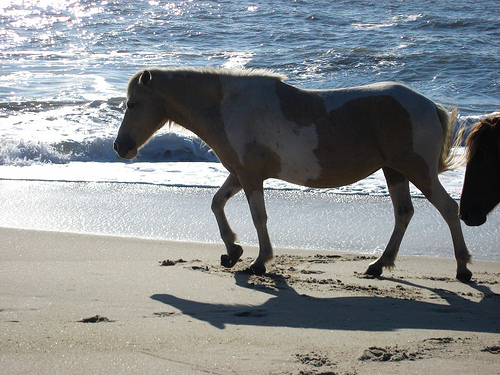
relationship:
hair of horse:
[187, 86, 445, 211] [83, 29, 494, 318]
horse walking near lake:
[109, 66, 476, 284] [0, 1, 499, 184]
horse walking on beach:
[109, 66, 476, 284] [0, 0, 499, 370]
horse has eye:
[66, 39, 490, 309] [121, 84, 147, 114]